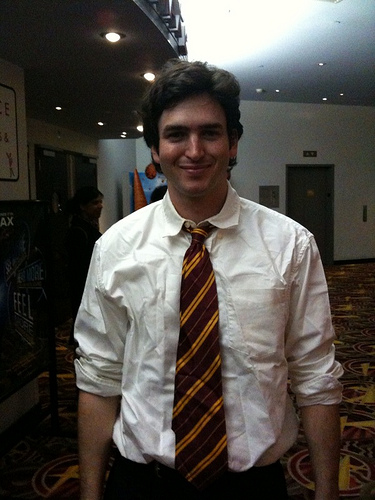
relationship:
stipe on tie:
[189, 223, 206, 243] [172, 217, 231, 471]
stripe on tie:
[172, 229, 227, 483] [157, 225, 249, 469]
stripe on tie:
[172, 229, 227, 483] [166, 217, 233, 463]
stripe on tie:
[172, 364, 218, 418] [160, 220, 241, 489]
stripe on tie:
[172, 229, 227, 483] [165, 222, 218, 496]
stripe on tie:
[172, 229, 227, 483] [172, 225, 242, 472]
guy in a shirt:
[72, 60, 344, 500] [88, 208, 330, 469]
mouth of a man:
[170, 156, 217, 179] [115, 51, 269, 231]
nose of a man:
[178, 130, 216, 165] [121, 43, 256, 241]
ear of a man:
[141, 129, 169, 171] [115, 51, 269, 231]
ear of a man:
[221, 119, 245, 174] [114, 53, 260, 260]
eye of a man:
[198, 122, 229, 143] [121, 43, 256, 241]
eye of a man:
[163, 127, 186, 147] [121, 43, 256, 241]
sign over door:
[298, 143, 321, 161] [282, 157, 348, 272]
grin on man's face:
[178, 162, 212, 175] [112, 57, 268, 232]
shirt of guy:
[74, 190, 339, 467] [72, 60, 344, 500]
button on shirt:
[185, 220, 192, 230] [74, 190, 339, 467]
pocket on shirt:
[236, 287, 286, 365] [74, 190, 339, 467]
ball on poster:
[142, 158, 156, 180] [125, 159, 168, 214]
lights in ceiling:
[46, 28, 350, 147] [3, 3, 373, 138]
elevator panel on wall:
[361, 203, 370, 221] [148, 101, 373, 263]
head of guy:
[150, 90, 234, 197] [72, 60, 344, 500]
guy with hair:
[72, 60, 344, 500] [132, 59, 245, 153]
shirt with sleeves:
[74, 190, 339, 467] [70, 280, 338, 412]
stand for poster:
[3, 197, 61, 424] [1, 210, 45, 385]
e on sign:
[3, 96, 13, 117] [1, 83, 20, 181]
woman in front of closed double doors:
[68, 183, 117, 332] [35, 142, 97, 232]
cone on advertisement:
[132, 165, 153, 212] [125, 171, 180, 215]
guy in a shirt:
[72, 60, 344, 500] [74, 190, 339, 467]